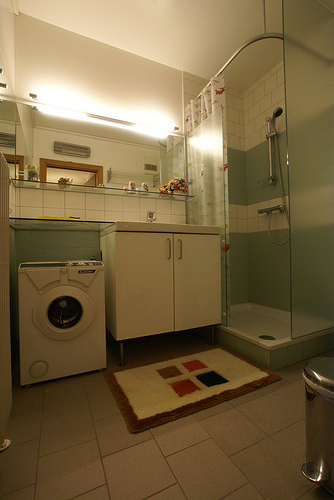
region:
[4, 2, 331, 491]
interior of residential bathroom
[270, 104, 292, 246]
shower head with hose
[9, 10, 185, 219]
mirror on bathroom wall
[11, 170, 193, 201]
items on glass shelf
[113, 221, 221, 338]
two doors on cabinet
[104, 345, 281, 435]
rug with four squares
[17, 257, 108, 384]
appliance with round window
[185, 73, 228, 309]
shower curtain on rod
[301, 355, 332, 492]
metal can with lid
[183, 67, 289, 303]
green and white wall tiles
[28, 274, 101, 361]
White washing machine in room.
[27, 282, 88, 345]
Washing machine is front loader.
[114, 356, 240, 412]
Bathmat on floor in bathroom.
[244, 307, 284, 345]
Floor of shower is white.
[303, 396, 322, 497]
Silver trash can in room.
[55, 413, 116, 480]
Ground is gray in color.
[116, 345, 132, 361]
Silver legs on cupboard in bathroom.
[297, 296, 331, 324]
Glass door on shower.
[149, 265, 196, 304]
White cupboards in bathroom.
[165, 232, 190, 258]
Silver handles on cupboard in bathroom.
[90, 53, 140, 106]
this is the wall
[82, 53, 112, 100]
the wall is white in color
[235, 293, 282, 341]
this is a sink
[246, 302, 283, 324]
the sink is white in color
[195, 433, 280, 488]
this is the floor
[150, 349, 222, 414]
this is a door matt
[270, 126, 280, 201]
this is a pipe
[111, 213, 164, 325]
this is a refrigerator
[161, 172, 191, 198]
this is a flower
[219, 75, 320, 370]
Shower stall in bathroom.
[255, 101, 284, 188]
Hand held shower attachement.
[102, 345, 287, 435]
Rug on bathroom floor.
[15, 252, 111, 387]
Washing machine in bathroom.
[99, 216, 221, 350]
Cabinet with sink in bathroom.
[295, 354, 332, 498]
Trash can in bathroom.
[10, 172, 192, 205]
Glass shelf above sink and cabinet.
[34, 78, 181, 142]
Lights above mirror in bathroom.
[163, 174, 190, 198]
Vase of flowers sitting on glass shelf.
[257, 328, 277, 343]
Water drain in shower stall.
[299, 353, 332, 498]
a trash bin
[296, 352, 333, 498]
a stainless steel trash bin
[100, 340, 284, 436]
a rug on floor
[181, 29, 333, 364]
a shower area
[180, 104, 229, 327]
a glass wall in the shower area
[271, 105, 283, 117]
a shower head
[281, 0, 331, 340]
a glass in the shower area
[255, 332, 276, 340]
a drainage in the shower area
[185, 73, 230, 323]
a shower curtain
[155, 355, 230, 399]
a pattern on the rug